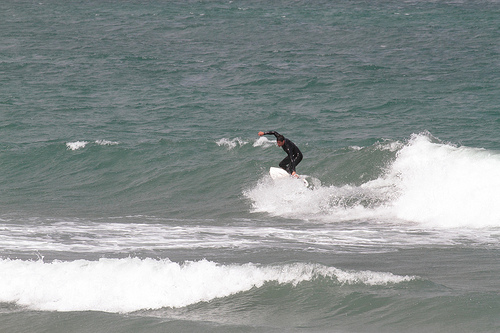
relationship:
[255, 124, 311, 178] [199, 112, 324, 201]
man participate sport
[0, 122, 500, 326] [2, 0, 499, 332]
waves in ocean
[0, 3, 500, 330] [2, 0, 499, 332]
ripples in ocean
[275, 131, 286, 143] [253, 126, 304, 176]
hair on surfer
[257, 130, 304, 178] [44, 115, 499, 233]
man surfing wave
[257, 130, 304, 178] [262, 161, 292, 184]
man falling off surfboard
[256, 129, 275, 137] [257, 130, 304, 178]
hand of man